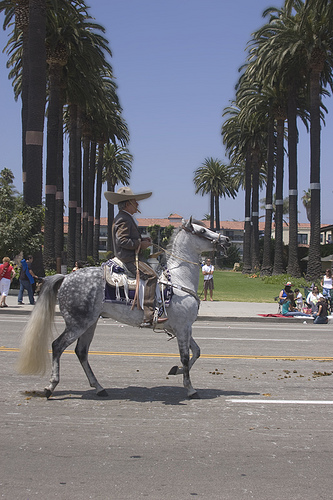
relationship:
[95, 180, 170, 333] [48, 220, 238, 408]
man riding a horse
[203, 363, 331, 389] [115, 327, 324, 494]
dirt on street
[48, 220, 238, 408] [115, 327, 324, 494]
horse in street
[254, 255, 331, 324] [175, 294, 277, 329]
people at sidewalk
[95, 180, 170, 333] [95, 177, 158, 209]
man wearing hat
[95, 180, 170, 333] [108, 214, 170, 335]
man wearing costume